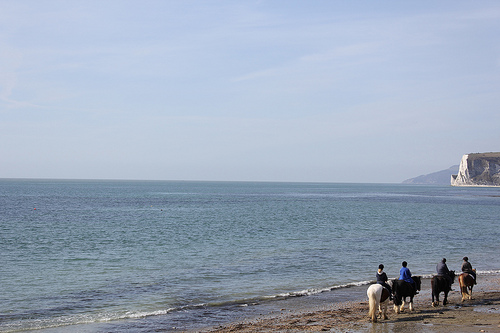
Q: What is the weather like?
A: Sunny.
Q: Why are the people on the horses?
A: Riding.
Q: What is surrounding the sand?
A: Water.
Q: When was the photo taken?
A: Day time.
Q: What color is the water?
A: Blue.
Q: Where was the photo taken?
A: The beach.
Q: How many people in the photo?
A: Four.